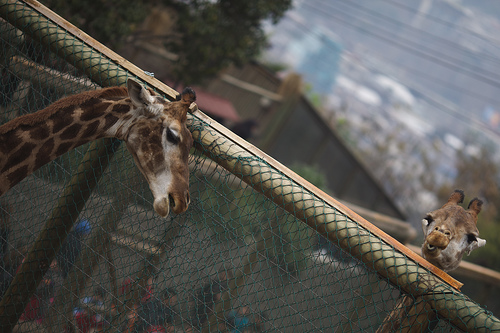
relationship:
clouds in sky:
[253, 0, 500, 234] [268, 2, 498, 241]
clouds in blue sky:
[253, 0, 500, 234] [259, 0, 497, 232]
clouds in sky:
[394, 52, 487, 112] [261, 8, 494, 250]